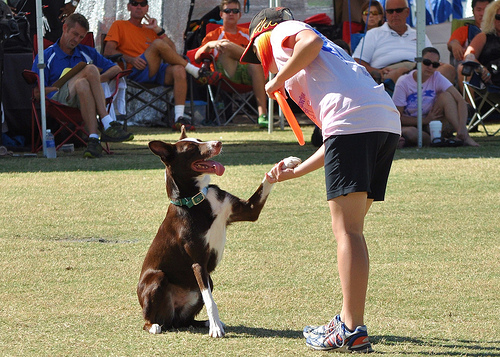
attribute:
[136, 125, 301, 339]
dog — shaking, brown, white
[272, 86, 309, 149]
frisbee — orange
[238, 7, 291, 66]
cap — black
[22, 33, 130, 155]
chair — red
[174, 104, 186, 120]
sock — white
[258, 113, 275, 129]
shoes — green